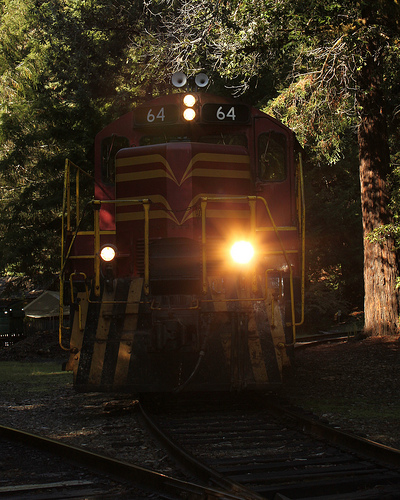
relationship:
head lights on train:
[98, 243, 120, 264] [61, 90, 305, 394]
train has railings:
[48, 64, 309, 402] [1, 380, 398, 498]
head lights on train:
[93, 228, 283, 292] [56, 68, 367, 399]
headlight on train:
[231, 239, 256, 264] [48, 64, 309, 402]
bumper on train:
[64, 276, 302, 385] [48, 64, 309, 402]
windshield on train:
[247, 129, 297, 194] [61, 58, 317, 391]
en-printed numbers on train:
[142, 104, 243, 124] [61, 90, 305, 394]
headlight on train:
[231, 239, 256, 264] [61, 86, 358, 355]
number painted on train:
[216, 106, 236, 122] [51, 71, 306, 393]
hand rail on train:
[56, 155, 309, 353] [61, 90, 305, 394]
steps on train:
[58, 206, 118, 285] [34, 71, 333, 356]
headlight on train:
[226, 228, 268, 271] [61, 58, 317, 391]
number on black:
[147, 108, 166, 123] [200, 102, 245, 126]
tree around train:
[0, 0, 400, 339] [80, 101, 350, 438]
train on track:
[48, 64, 309, 402] [4, 383, 398, 497]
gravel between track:
[2, 377, 224, 494] [136, 385, 398, 497]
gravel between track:
[2, 377, 227, 492] [1, 424, 248, 499]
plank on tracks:
[246, 470, 395, 497] [129, 389, 398, 499]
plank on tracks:
[221, 453, 397, 485] [129, 389, 398, 499]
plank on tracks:
[207, 443, 369, 473] [129, 389, 398, 499]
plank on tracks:
[185, 430, 351, 459] [129, 389, 398, 499]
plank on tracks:
[174, 427, 333, 443] [129, 389, 398, 499]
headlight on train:
[231, 239, 256, 264] [61, 58, 317, 391]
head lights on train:
[98, 243, 120, 264] [61, 58, 317, 391]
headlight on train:
[183, 108, 196, 122] [61, 58, 317, 391]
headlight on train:
[183, 94, 196, 107] [61, 58, 317, 391]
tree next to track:
[22, 0, 399, 344] [1, 424, 248, 499]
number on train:
[136, 104, 171, 127] [48, 64, 309, 402]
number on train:
[210, 100, 239, 124] [48, 64, 309, 402]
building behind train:
[20, 288, 70, 341] [48, 64, 309, 402]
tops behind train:
[3, 2, 396, 87] [48, 64, 309, 402]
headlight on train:
[183, 108, 196, 122] [48, 64, 309, 402]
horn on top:
[171, 68, 187, 89] [129, 70, 270, 107]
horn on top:
[188, 72, 212, 90] [129, 70, 270, 107]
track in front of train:
[4, 383, 398, 497] [61, 58, 317, 391]